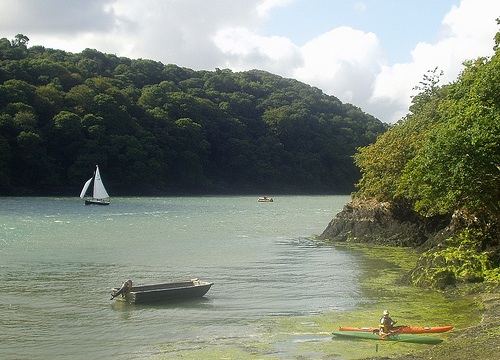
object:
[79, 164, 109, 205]
sailboat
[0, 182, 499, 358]
bay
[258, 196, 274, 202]
raft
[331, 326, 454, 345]
kayak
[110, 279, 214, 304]
boat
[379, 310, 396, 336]
person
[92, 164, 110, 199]
drap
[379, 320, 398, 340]
oar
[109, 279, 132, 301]
motor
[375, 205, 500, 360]
shore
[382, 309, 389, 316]
hat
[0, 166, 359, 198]
bank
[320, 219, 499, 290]
rock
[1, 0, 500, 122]
sky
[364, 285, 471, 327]
algae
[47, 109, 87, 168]
tree